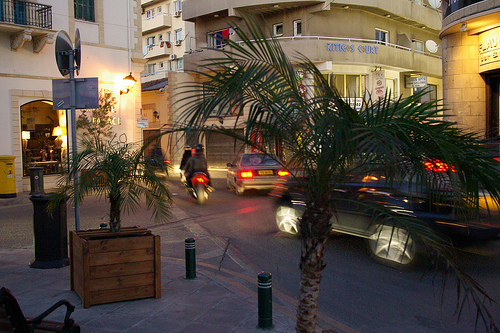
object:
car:
[270, 160, 499, 271]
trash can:
[27, 167, 46, 196]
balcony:
[0, 0, 58, 54]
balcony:
[183, 35, 444, 81]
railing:
[0, 0, 52, 29]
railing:
[184, 35, 443, 60]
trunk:
[294, 205, 333, 333]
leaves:
[451, 278, 461, 319]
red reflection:
[237, 204, 256, 215]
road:
[0, 168, 498, 331]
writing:
[326, 42, 380, 55]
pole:
[183, 235, 196, 277]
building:
[0, 1, 148, 195]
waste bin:
[26, 192, 71, 270]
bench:
[0, 286, 82, 333]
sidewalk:
[0, 249, 298, 332]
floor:
[0, 165, 500, 332]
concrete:
[0, 248, 322, 330]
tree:
[129, 12, 499, 332]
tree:
[44, 129, 176, 234]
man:
[179, 146, 193, 170]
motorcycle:
[179, 167, 209, 207]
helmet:
[195, 144, 206, 153]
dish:
[425, 39, 437, 54]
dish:
[427, 0, 441, 8]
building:
[167, 0, 442, 174]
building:
[438, 0, 500, 159]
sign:
[51, 77, 99, 110]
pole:
[67, 50, 81, 231]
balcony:
[142, 12, 172, 34]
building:
[139, 0, 196, 173]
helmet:
[184, 146, 192, 152]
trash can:
[0, 155, 17, 200]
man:
[183, 144, 213, 189]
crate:
[68, 226, 161, 310]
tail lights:
[241, 171, 252, 177]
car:
[224, 149, 292, 199]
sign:
[54, 29, 74, 78]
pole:
[256, 271, 274, 330]